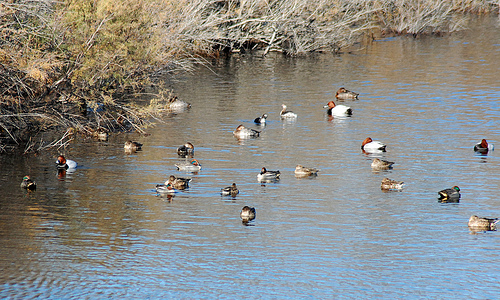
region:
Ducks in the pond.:
[7, 6, 497, 288]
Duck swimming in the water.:
[47, 151, 90, 177]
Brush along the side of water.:
[2, 6, 194, 135]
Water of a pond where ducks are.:
[29, 236, 466, 286]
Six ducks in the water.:
[347, 136, 499, 251]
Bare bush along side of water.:
[249, 11, 369, 59]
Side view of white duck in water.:
[317, 99, 367, 129]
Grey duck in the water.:
[429, 184, 472, 207]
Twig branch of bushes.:
[92, 13, 104, 43]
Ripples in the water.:
[14, 269, 253, 297]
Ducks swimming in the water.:
[10, 52, 497, 258]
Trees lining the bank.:
[2, 5, 175, 150]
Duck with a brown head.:
[317, 96, 356, 124]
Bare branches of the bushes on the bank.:
[180, 1, 480, 66]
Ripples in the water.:
[2, 237, 128, 299]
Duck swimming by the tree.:
[156, 87, 203, 125]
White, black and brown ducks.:
[315, 97, 396, 159]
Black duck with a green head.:
[434, 180, 466, 205]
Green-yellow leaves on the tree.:
[54, 2, 157, 81]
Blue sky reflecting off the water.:
[104, 238, 499, 298]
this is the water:
[18, 207, 160, 288]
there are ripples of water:
[20, 240, 195, 299]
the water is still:
[63, 225, 157, 280]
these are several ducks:
[146, 132, 499, 252]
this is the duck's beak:
[320, 103, 328, 110]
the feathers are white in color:
[332, 106, 342, 114]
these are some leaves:
[74, 2, 127, 64]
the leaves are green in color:
[81, 5, 131, 42]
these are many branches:
[206, 5, 332, 43]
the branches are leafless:
[36, 105, 75, 135]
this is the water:
[126, 220, 190, 287]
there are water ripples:
[71, 225, 210, 293]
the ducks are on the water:
[207, 85, 394, 220]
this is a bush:
[3, 2, 180, 89]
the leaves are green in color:
[70, 3, 93, 30]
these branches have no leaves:
[9, 101, 147, 129]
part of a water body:
[357, 206, 426, 248]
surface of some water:
[300, 223, 332, 262]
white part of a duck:
[337, 105, 344, 112]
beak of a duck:
[321, 103, 333, 113]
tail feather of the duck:
[435, 190, 452, 209]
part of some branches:
[86, 50, 135, 85]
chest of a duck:
[238, 212, 255, 220]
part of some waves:
[280, 215, 342, 271]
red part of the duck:
[478, 136, 489, 149]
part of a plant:
[58, 46, 83, 77]